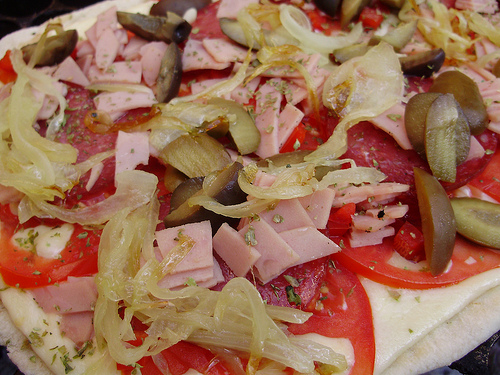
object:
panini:
[2, 0, 497, 373]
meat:
[364, 182, 411, 196]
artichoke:
[414, 166, 456, 277]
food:
[1, 1, 498, 373]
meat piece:
[113, 130, 150, 188]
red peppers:
[394, 220, 423, 259]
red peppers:
[324, 76, 497, 199]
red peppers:
[37, 27, 151, 191]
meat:
[287, 67, 331, 91]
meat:
[237, 218, 299, 281]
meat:
[279, 227, 343, 269]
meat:
[138, 247, 212, 289]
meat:
[254, 77, 282, 158]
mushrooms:
[114, 12, 172, 42]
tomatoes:
[330, 235, 499, 289]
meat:
[246, 186, 316, 232]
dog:
[254, 77, 283, 159]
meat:
[155, 220, 213, 274]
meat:
[259, 174, 335, 230]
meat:
[213, 222, 261, 277]